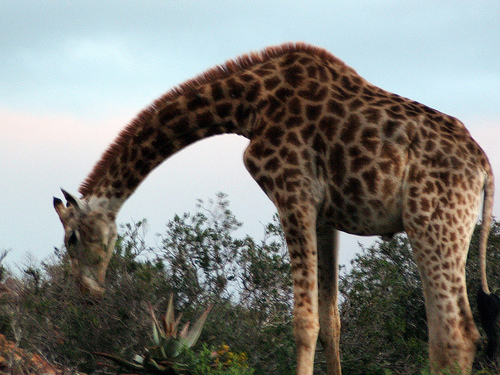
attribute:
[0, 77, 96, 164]
clouds — white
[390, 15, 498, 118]
clouds — white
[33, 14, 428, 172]
sky — blue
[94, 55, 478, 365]
giraffe — brown, tan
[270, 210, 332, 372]
leg — brown, white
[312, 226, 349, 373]
leg — brown, white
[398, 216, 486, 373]
leg — brown, white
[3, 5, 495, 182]
sky — blue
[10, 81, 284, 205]
clouds — white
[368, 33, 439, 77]
sky — blue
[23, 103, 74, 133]
clouds — white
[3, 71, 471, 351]
giraffe — bent over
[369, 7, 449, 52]
clouds — white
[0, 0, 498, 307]
sky — blue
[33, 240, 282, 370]
plants — green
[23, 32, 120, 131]
clouds — white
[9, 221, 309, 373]
branches — distant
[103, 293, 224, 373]
plant — white , pink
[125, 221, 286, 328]
foilage — brown, green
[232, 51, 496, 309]
body — brown, white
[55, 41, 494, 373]
giraffe — spotted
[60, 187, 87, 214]
ear — brown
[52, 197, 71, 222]
ear — brown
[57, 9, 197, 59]
sky — blue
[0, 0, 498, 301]
clouds — white